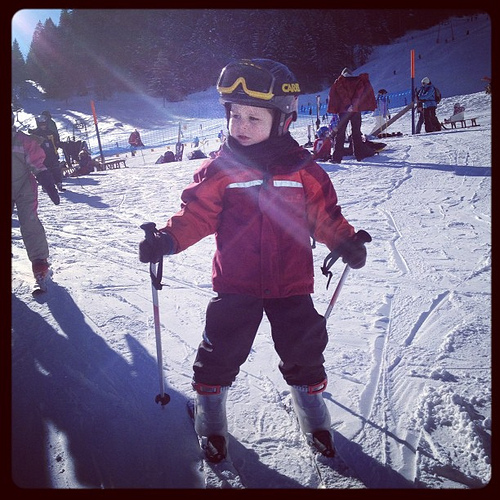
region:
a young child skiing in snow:
[141, 57, 368, 489]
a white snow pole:
[142, 219, 174, 408]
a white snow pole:
[319, 228, 372, 318]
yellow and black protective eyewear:
[214, 60, 274, 97]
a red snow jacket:
[166, 141, 358, 296]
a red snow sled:
[434, 102, 479, 132]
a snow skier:
[13, 104, 55, 295]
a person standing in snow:
[327, 55, 377, 157]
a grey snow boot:
[189, 384, 230, 459]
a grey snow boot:
[284, 377, 336, 455]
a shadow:
[34, 313, 154, 468]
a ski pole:
[148, 285, 173, 363]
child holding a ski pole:
[339, 244, 356, 284]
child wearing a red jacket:
[204, 163, 316, 289]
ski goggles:
[216, 68, 272, 98]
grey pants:
[201, 309, 247, 371]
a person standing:
[418, 77, 450, 134]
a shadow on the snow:
[61, 183, 116, 221]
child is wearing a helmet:
[270, 65, 305, 113]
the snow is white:
[373, 172, 463, 247]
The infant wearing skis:
[137, 59, 382, 465]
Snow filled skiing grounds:
[12, 20, 492, 490]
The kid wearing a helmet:
[138, 48, 365, 460]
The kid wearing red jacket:
[141, 59, 369, 461]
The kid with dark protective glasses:
[141, 59, 371, 465]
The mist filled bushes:
[11, 5, 492, 100]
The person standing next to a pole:
[407, 46, 442, 136]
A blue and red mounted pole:
[88, 97, 108, 172]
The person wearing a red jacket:
[316, 66, 377, 166]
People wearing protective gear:
[14, 59, 462, 462]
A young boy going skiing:
[140, 38, 455, 469]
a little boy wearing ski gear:
[122, 48, 477, 496]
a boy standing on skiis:
[131, 41, 372, 496]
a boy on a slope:
[81, 31, 458, 487]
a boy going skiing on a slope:
[120, 46, 415, 496]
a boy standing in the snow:
[122, 40, 462, 490]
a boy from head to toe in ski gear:
[126, 33, 451, 498]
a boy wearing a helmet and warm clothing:
[115, 35, 491, 498]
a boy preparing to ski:
[112, 37, 435, 497]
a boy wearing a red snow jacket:
[145, 42, 494, 462]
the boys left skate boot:
[190, 382, 222, 445]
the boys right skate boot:
[280, 382, 342, 461]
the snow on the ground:
[397, 381, 466, 447]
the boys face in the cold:
[222, 94, 274, 151]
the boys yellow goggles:
[214, 54, 277, 105]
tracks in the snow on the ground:
[372, 194, 441, 261]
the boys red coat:
[200, 157, 339, 262]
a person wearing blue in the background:
[409, 78, 456, 130]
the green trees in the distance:
[35, 22, 70, 44]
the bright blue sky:
[21, 13, 33, 27]